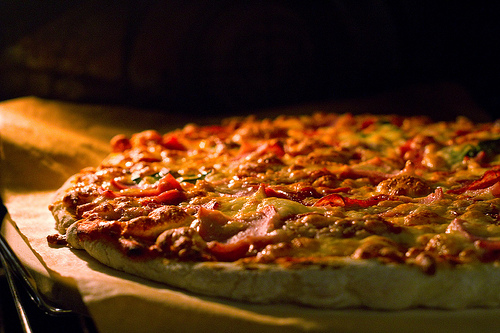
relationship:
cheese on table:
[47, 111, 499, 309] [0, 100, 498, 331]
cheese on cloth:
[47, 111, 499, 309] [1, 94, 498, 329]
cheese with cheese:
[47, 111, 499, 309] [217, 190, 319, 217]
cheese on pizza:
[69, 118, 499, 263] [45, 81, 498, 312]